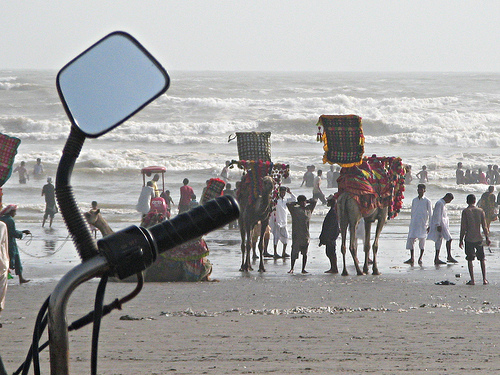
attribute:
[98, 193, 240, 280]
grip — black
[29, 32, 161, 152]
mirror — rear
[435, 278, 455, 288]
trash — dark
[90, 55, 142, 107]
sky — blue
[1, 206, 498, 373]
beach — sandy, wet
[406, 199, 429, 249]
tunic — white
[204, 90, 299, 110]
foam — white